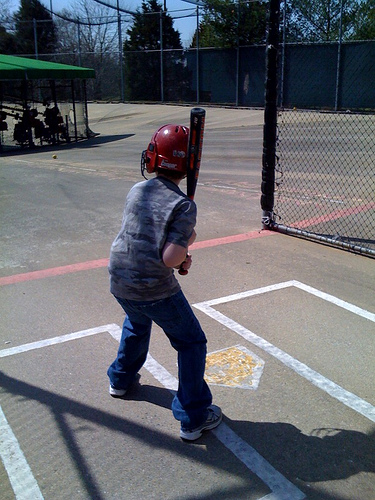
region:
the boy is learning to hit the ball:
[79, 91, 255, 439]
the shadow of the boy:
[106, 385, 368, 490]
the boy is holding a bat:
[107, 66, 220, 228]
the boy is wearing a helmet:
[110, 81, 215, 210]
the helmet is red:
[136, 118, 220, 189]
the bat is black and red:
[155, 77, 243, 224]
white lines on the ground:
[250, 255, 363, 411]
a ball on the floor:
[26, 137, 73, 181]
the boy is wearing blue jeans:
[84, 256, 231, 404]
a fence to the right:
[244, 41, 367, 226]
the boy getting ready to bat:
[106, 109, 237, 439]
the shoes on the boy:
[100, 373, 223, 439]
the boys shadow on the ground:
[210, 395, 373, 480]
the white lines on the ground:
[198, 257, 359, 364]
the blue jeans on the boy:
[102, 281, 212, 426]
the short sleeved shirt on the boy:
[106, 173, 196, 300]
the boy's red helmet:
[143, 125, 191, 173]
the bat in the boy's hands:
[177, 100, 206, 277]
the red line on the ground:
[11, 238, 105, 294]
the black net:
[267, 33, 373, 230]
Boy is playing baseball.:
[104, 107, 224, 442]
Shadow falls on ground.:
[18, 362, 306, 498]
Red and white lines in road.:
[30, 227, 301, 405]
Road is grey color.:
[9, 173, 80, 274]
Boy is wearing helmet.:
[121, 120, 218, 211]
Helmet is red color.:
[125, 117, 213, 194]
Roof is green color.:
[2, 51, 77, 89]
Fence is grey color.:
[81, 17, 303, 90]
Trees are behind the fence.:
[22, 11, 344, 93]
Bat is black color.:
[156, 106, 211, 252]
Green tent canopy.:
[1, 58, 118, 91]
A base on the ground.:
[189, 334, 276, 404]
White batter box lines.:
[6, 304, 374, 490]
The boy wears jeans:
[98, 278, 233, 439]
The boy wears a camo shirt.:
[98, 171, 200, 308]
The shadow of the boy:
[228, 406, 372, 494]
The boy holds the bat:
[183, 229, 196, 276]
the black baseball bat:
[178, 99, 209, 210]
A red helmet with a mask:
[136, 113, 187, 188]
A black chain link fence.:
[290, 14, 360, 227]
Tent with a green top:
[1, 51, 113, 141]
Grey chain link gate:
[252, 6, 366, 254]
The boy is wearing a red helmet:
[116, 100, 245, 201]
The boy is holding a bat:
[91, 104, 248, 311]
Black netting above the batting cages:
[34, 1, 292, 36]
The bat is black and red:
[167, 89, 213, 277]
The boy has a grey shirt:
[72, 109, 248, 310]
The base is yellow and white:
[195, 324, 289, 411]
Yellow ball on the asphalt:
[40, 148, 69, 163]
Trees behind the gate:
[21, 5, 255, 95]